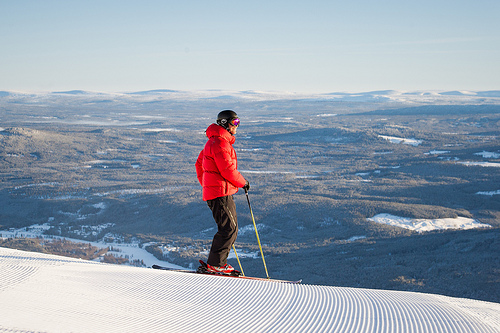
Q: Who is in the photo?
A: A man.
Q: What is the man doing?
A: Skiing.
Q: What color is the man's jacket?
A: Red.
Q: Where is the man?
A: On top of a hill.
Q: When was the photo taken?
A: During the day.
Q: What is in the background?
A: Mountains.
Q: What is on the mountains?
A: Snow.